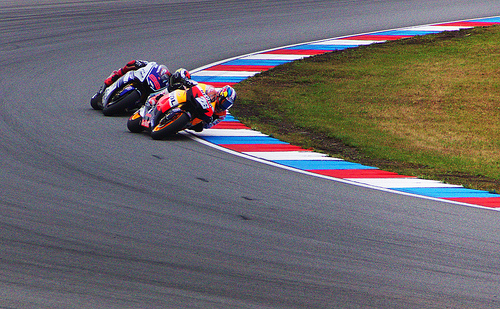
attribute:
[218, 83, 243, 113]
helmet — multicolor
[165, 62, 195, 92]
helmet — multicolor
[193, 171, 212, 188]
mark — small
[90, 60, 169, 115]
motorcycle — blue, white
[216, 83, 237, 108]
helmet — colorful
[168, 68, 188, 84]
helmet — colorful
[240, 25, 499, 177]
grass — beautiful , clean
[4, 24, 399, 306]
track — curved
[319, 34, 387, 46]
stripe — Red and blue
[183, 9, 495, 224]
stripe — Red and blue, red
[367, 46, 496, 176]
sand — empty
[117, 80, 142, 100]
fender — royal blue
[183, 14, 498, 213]
colors — mutlple 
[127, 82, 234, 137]
biker — multi-colored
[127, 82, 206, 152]
motorcycle — yellow, red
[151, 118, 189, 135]
wheel — bike's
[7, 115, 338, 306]
road — clean, neat 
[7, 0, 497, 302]
pavement — black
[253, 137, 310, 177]
stripes — Red and blue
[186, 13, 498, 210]
stripe — Red and blue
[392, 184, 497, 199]
stripe — Red and blue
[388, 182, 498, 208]
stripe — Red and blue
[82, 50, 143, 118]
bike — blue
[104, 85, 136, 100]
front tire — the front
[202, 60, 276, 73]
stripe — Red and blue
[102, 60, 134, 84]
pant leg — red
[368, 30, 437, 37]
stripe — Red and blue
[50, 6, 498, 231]
curve — large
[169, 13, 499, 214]
stripes — blue, white, red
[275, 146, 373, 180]
street — red white and blue 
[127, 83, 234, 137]
bike — player's